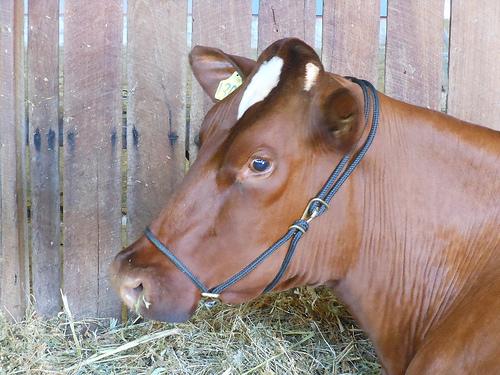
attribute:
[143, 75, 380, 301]
rope — blue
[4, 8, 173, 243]
fence — brown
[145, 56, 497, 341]
cow — brown, pretty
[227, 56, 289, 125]
spot — white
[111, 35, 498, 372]
cow — brown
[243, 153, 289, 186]
eye — black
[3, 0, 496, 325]
fence — wooden, brown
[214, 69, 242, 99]
tag — white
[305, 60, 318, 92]
white — little, speck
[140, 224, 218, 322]
muzzle — blue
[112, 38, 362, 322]
face — brown, beautiful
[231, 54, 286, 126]
pattern — white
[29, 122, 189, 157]
stains — black